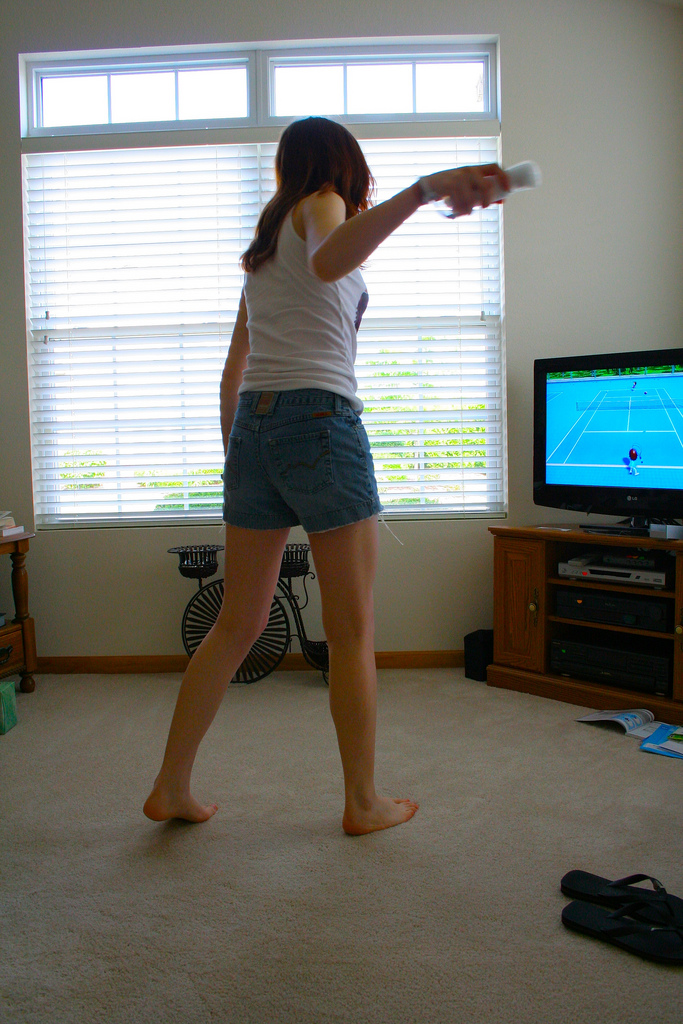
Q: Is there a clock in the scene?
A: No, there are no clocks.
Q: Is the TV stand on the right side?
A: Yes, the TV stand is on the right of the image.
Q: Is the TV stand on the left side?
A: No, the TV stand is on the right of the image.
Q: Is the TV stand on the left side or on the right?
A: The TV stand is on the right of the image.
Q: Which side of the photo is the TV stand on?
A: The TV stand is on the right of the image.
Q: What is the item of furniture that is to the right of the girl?
A: The piece of furniture is a TV stand.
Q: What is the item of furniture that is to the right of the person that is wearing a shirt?
A: The piece of furniture is a TV stand.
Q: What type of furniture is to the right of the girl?
A: The piece of furniture is a TV stand.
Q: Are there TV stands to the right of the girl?
A: Yes, there is a TV stand to the right of the girl.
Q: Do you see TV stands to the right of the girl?
A: Yes, there is a TV stand to the right of the girl.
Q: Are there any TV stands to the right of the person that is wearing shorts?
A: Yes, there is a TV stand to the right of the girl.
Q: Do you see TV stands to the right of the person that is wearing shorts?
A: Yes, there is a TV stand to the right of the girl.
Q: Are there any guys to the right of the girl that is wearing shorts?
A: No, there is a TV stand to the right of the girl.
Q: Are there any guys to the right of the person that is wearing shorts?
A: No, there is a TV stand to the right of the girl.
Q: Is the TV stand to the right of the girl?
A: Yes, the TV stand is to the right of the girl.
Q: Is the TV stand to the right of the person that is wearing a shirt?
A: Yes, the TV stand is to the right of the girl.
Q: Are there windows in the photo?
A: Yes, there is a window.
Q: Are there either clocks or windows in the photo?
A: Yes, there is a window.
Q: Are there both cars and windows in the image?
A: No, there is a window but no cars.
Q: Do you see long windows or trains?
A: Yes, there is a long window.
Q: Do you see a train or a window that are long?
A: Yes, the window is long.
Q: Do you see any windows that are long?
A: Yes, there is a long window.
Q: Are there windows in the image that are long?
A: Yes, there is a window that is long.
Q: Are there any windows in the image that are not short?
A: Yes, there is a long window.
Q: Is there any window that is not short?
A: Yes, there is a long window.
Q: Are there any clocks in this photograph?
A: No, there are no clocks.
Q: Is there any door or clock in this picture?
A: No, there are no clocks or doors.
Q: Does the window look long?
A: Yes, the window is long.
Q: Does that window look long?
A: Yes, the window is long.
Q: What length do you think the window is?
A: The window is long.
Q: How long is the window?
A: The window is long.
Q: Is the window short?
A: No, the window is long.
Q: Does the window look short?
A: No, the window is long.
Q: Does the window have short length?
A: No, the window is long.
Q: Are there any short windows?
A: No, there is a window but it is long.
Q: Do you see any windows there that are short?
A: No, there is a window but it is long.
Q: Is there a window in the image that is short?
A: No, there is a window but it is long.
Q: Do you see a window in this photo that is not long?
A: No, there is a window but it is long.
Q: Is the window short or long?
A: The window is long.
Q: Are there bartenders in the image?
A: No, there are no bartenders.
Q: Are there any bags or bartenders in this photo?
A: No, there are no bartenders or bags.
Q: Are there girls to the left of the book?
A: Yes, there is a girl to the left of the book.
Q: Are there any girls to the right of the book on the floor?
A: No, the girl is to the left of the book.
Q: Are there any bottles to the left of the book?
A: No, there is a girl to the left of the book.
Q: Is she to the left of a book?
A: Yes, the girl is to the left of a book.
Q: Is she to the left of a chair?
A: No, the girl is to the left of a book.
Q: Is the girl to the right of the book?
A: No, the girl is to the left of the book.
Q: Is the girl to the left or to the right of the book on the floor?
A: The girl is to the left of the book.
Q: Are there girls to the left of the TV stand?
A: Yes, there is a girl to the left of the TV stand.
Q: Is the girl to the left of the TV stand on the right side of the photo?
A: Yes, the girl is to the left of the TV stand.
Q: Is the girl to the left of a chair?
A: No, the girl is to the left of the TV stand.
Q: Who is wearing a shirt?
A: The girl is wearing a shirt.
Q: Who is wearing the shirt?
A: The girl is wearing a shirt.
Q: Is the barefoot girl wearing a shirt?
A: Yes, the girl is wearing a shirt.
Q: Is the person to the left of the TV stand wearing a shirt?
A: Yes, the girl is wearing a shirt.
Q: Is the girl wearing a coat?
A: No, the girl is wearing a shirt.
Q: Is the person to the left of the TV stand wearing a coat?
A: No, the girl is wearing a shirt.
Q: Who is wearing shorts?
A: The girl is wearing shorts.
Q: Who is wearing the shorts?
A: The girl is wearing shorts.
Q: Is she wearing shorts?
A: Yes, the girl is wearing shorts.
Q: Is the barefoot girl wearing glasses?
A: No, the girl is wearing shorts.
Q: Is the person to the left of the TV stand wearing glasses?
A: No, the girl is wearing shorts.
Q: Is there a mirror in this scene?
A: No, there are no mirrors.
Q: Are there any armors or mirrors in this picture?
A: No, there are no mirrors or armors.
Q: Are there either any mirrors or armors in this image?
A: No, there are no mirrors or armors.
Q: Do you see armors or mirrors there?
A: No, there are no mirrors or armors.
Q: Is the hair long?
A: Yes, the hair is long.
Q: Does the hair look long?
A: Yes, the hair is long.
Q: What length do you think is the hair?
A: The hair is long.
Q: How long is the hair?
A: The hair is long.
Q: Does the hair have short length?
A: No, the hair is long.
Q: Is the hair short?
A: No, the hair is long.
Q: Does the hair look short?
A: No, the hair is long.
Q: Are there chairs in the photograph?
A: No, there are no chairs.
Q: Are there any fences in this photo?
A: No, there are no fences.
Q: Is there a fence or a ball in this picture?
A: No, there are no fences or balls.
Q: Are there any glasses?
A: No, there are no glasses.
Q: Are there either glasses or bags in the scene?
A: No, there are no glasses or bags.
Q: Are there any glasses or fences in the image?
A: No, there are no glasses or fences.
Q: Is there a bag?
A: No, there are no bags.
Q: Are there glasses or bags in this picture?
A: No, there are no bags or glasses.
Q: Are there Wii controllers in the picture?
A: Yes, there is a Wii controller.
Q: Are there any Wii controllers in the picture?
A: Yes, there is a Wii controller.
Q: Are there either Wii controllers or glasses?
A: Yes, there is a Wii controller.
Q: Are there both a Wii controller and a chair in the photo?
A: No, there is a Wii controller but no chairs.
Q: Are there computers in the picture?
A: No, there are no computers.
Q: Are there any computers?
A: No, there are no computers.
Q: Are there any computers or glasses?
A: No, there are no computers or glasses.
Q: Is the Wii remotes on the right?
A: Yes, the Wii remotes is on the right of the image.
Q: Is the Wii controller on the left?
A: No, the Wii controller is on the right of the image.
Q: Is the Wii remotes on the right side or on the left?
A: The Wii remotes is on the right of the image.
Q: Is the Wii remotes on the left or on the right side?
A: The Wii remotes is on the right of the image.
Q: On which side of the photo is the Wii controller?
A: The Wii controller is on the right of the image.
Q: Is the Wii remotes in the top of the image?
A: Yes, the Wii remotes is in the top of the image.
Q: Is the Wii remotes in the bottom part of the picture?
A: No, the Wii remotes is in the top of the image.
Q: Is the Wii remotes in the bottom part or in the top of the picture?
A: The Wii remotes is in the top of the image.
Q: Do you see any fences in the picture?
A: No, there are no fences.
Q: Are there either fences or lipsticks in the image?
A: No, there are no fences or lipsticks.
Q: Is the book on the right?
A: Yes, the book is on the right of the image.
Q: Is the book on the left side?
A: No, the book is on the right of the image.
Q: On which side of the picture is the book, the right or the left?
A: The book is on the right of the image.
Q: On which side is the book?
A: The book is on the right of the image.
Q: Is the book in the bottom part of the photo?
A: Yes, the book is in the bottom of the image.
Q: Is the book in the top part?
A: No, the book is in the bottom of the image.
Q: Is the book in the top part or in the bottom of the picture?
A: The book is in the bottom of the image.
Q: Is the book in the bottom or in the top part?
A: The book is in the bottom of the image.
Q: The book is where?
A: The book is on the floor.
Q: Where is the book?
A: The book is on the floor.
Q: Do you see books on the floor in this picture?
A: Yes, there is a book on the floor.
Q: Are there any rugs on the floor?
A: No, there is a book on the floor.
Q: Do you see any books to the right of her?
A: Yes, there is a book to the right of the girl.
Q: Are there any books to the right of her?
A: Yes, there is a book to the right of the girl.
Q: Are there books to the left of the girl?
A: No, the book is to the right of the girl.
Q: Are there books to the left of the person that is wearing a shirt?
A: No, the book is to the right of the girl.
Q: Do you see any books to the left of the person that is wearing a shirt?
A: No, the book is to the right of the girl.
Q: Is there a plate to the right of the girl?
A: No, there is a book to the right of the girl.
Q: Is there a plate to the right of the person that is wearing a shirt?
A: No, there is a book to the right of the girl.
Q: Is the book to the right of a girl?
A: Yes, the book is to the right of a girl.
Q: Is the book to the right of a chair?
A: No, the book is to the right of a girl.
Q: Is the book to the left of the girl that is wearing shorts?
A: No, the book is to the right of the girl.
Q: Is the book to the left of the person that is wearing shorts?
A: No, the book is to the right of the girl.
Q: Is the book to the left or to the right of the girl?
A: The book is to the right of the girl.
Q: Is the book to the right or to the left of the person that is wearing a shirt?
A: The book is to the right of the girl.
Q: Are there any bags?
A: No, there are no bags.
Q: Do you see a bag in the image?
A: No, there are no bags.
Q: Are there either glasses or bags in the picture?
A: No, there are no bags or glasses.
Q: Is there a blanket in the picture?
A: No, there are no blankets.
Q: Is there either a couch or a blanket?
A: No, there are no blankets or couches.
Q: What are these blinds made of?
A: The blinds are made of plastic.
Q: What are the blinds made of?
A: The blinds are made of plastic.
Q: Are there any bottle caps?
A: No, there are no bottle caps.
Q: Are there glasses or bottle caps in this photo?
A: No, there are no bottle caps or glasses.